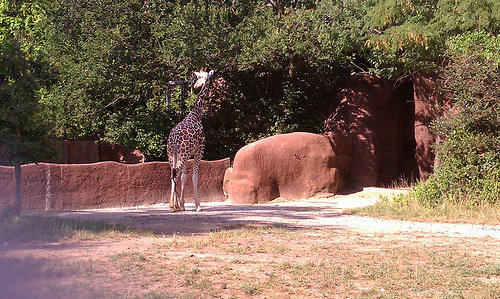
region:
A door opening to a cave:
[382, 64, 429, 201]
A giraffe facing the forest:
[168, 64, 215, 227]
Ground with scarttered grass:
[104, 204, 411, 289]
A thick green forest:
[28, 11, 393, 113]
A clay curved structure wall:
[223, 138, 348, 205]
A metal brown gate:
[21, 129, 144, 161]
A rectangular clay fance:
[23, 161, 230, 205]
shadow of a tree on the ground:
[42, 193, 345, 232]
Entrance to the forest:
[318, 48, 475, 192]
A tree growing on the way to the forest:
[4, 40, 54, 231]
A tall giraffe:
[170, 59, 215, 216]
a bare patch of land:
[88, 207, 302, 228]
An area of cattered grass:
[3, 221, 493, 298]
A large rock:
[226, 131, 334, 205]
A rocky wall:
[0, 164, 232, 216]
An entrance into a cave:
[356, 74, 441, 196]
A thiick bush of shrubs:
[1, 2, 482, 147]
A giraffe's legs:
[165, 160, 211, 212]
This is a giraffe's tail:
[166, 146, 180, 190]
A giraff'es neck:
[191, 84, 203, 117]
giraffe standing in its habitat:
[167, 65, 217, 227]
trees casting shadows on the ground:
[54, 188, 336, 235]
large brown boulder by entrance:
[224, 122, 341, 207]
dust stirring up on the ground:
[1, 165, 108, 295]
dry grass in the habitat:
[0, 194, 496, 295]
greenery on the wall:
[0, 17, 410, 144]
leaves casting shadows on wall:
[105, 143, 149, 158]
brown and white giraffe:
[165, 50, 220, 212]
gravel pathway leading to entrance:
[279, 151, 496, 234]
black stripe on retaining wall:
[10, 157, 26, 214]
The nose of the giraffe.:
[189, 86, 203, 93]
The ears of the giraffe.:
[197, 67, 217, 77]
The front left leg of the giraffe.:
[174, 154, 191, 220]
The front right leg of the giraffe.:
[190, 151, 205, 211]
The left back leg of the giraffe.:
[171, 162, 181, 211]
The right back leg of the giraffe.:
[176, 160, 191, 208]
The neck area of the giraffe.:
[189, 85, 211, 113]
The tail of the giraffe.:
[169, 140, 186, 178]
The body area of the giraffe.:
[167, 117, 197, 164]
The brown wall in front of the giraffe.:
[5, 153, 243, 193]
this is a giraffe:
[172, 66, 226, 211]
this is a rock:
[255, 134, 325, 189]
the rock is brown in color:
[272, 151, 315, 186]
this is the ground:
[140, 221, 332, 281]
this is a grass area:
[22, 213, 95, 243]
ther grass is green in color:
[29, 218, 65, 230]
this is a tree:
[247, 21, 335, 85]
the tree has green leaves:
[323, 22, 358, 48]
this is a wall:
[29, 166, 146, 198]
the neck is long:
[190, 84, 212, 109]